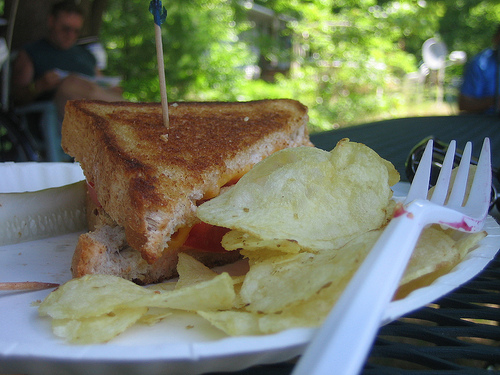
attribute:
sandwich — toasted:
[46, 77, 313, 289]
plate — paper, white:
[2, 192, 498, 369]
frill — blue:
[142, 0, 174, 27]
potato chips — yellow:
[30, 153, 464, 324]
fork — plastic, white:
[303, 93, 489, 375]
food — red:
[381, 187, 478, 240]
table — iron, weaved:
[0, 110, 500, 363]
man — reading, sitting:
[12, 5, 127, 156]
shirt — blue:
[455, 47, 499, 127]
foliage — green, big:
[107, 1, 461, 122]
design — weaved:
[322, 120, 499, 373]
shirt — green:
[22, 41, 104, 106]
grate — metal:
[340, 212, 466, 374]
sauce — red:
[158, 224, 234, 254]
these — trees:
[162, 10, 423, 104]